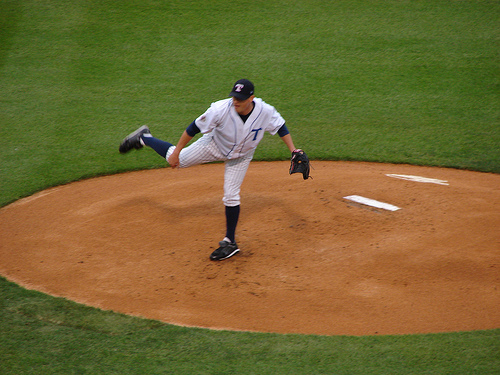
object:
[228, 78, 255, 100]
cap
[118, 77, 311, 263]
pitcher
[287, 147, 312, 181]
glove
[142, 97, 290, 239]
uniform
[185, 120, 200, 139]
shirt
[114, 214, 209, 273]
dirt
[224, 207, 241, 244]
sock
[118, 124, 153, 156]
shoe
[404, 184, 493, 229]
mound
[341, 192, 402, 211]
block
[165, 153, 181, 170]
hand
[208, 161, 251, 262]
leg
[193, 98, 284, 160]
jersey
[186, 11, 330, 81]
grass